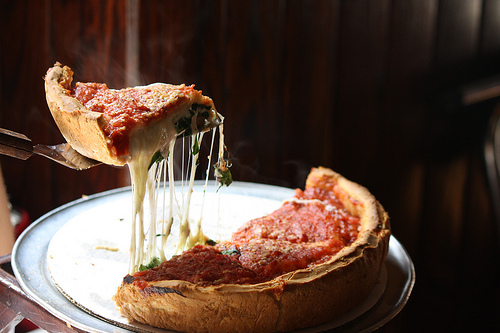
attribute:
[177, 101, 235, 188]
spinach — green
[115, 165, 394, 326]
pizza — slice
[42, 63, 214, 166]
pizza — slice